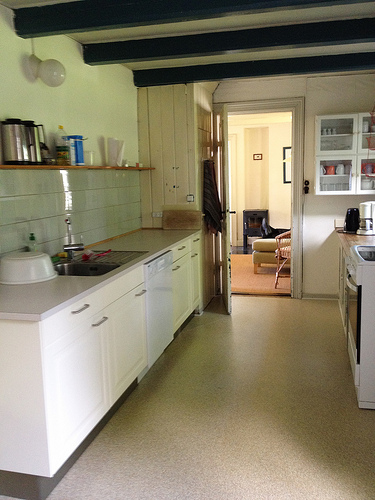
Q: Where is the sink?
A: On the counter.